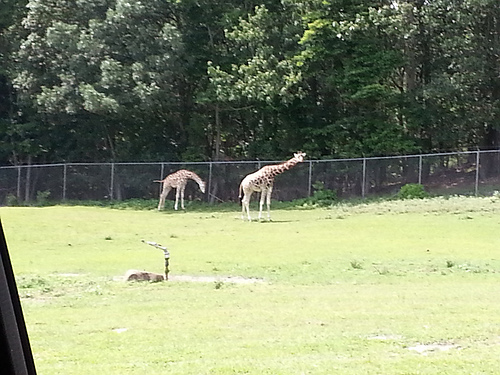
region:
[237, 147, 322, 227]
Giraffe looking up against a fence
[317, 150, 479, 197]
Chain link fence in front of trees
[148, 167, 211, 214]
Giraffe looking down at the ground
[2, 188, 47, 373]
Side of a window of a passing vehicle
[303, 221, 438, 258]
Green grass in a field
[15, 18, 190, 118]
Green leaves on several trees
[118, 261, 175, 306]
Rock in the middle of a field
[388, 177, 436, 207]
Small green bush in front of a fence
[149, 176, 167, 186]
Giraffe tail sticking straight out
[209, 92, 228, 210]
Bare tree trunk behind a fence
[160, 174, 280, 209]
two giraffes are seen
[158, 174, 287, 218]
giraffes are standing up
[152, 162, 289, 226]
the giraffes are spotted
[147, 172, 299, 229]
the giraffes are in grass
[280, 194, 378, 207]
shrubs by the fence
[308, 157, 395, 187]
the fence is gray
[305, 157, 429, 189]
the fence is metal and wire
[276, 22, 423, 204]
the trees are above fence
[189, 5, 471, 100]
the trees are green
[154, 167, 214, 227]
one giraffe is bent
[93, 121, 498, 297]
2 giraffes are pictured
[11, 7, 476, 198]
the trees are behind the fence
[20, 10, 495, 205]
the trees are green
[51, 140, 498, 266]
the fence is metal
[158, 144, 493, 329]
the giraffes are orange and brown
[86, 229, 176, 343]
a rock is in the grass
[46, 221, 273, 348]
the grass is green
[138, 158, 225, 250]
the giraffe has its head down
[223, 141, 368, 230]
the giraffe's neck is sticking out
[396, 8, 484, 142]
the trees branches are brown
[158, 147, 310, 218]
two giraffes in an enclosure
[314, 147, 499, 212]
metal chain link fence surrounding animal enclosure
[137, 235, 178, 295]
metal pipe protruding from the earth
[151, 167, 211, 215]
giraffe with their head bowed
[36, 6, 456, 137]
dense forest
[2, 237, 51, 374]
window edge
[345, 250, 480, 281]
tufts of tall green grass in a pasture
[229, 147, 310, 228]
giraffe standing in the sunlight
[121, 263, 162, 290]
flat rock in the middle of a pasture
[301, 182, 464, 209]
leafy vegetation growing in the shade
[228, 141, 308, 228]
a giraffe in a distance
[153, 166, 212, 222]
a giraffe in a distance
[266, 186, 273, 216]
the long leg of a giraffe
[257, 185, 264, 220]
the long leg of a giraffe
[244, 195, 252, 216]
the long leg of a giraffe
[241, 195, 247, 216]
the long leg of a giraffe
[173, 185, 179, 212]
the long leg of a giraffe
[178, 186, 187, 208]
the long leg of a giraffe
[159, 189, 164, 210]
the long leg of a giraffe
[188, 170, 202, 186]
the long neck of a giraffe